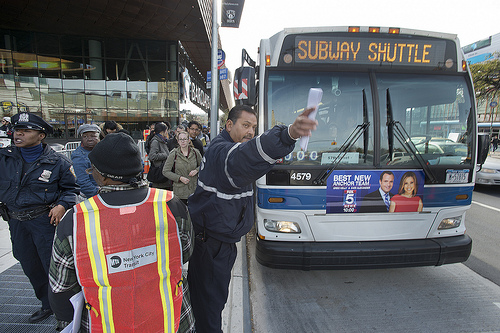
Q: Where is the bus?
A: On the street.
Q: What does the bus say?
A: Subway shuttle.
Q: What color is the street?
A: Gray.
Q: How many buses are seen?
A: One.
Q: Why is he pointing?
A: Giving directions.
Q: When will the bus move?
A: When driver drives.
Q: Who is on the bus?
A: People.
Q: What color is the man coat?
A: Black.